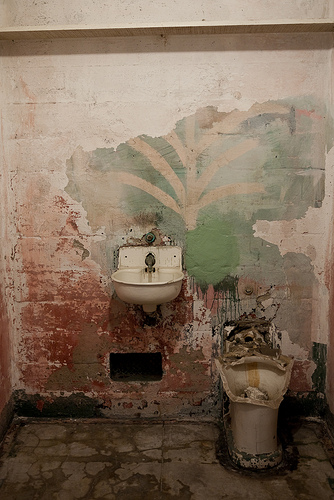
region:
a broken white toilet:
[209, 335, 296, 476]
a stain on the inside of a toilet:
[241, 366, 269, 398]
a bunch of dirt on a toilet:
[221, 436, 267, 476]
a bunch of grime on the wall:
[224, 311, 270, 336]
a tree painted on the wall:
[154, 138, 234, 221]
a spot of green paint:
[185, 221, 246, 290]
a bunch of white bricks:
[58, 87, 106, 131]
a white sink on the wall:
[121, 227, 213, 313]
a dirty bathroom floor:
[69, 434, 152, 486]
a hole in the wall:
[94, 346, 166, 389]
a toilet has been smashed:
[209, 301, 295, 474]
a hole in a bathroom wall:
[101, 341, 170, 389]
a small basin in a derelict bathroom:
[106, 229, 187, 316]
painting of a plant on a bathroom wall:
[108, 98, 294, 233]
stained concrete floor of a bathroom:
[2, 411, 332, 499]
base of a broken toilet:
[211, 351, 300, 473]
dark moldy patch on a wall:
[7, 388, 107, 423]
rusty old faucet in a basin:
[142, 252, 157, 276]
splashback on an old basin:
[116, 244, 184, 270]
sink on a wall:
[100, 233, 202, 305]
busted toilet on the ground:
[211, 347, 308, 480]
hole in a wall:
[105, 348, 169, 381]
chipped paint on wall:
[134, 123, 273, 230]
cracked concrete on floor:
[24, 423, 193, 478]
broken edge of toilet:
[237, 380, 278, 411]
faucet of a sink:
[140, 250, 160, 275]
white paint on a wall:
[82, 68, 176, 113]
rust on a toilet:
[244, 361, 263, 384]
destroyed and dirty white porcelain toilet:
[213, 317, 294, 470]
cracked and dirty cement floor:
[0, 417, 332, 498]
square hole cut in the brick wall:
[107, 349, 164, 383]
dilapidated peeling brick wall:
[3, 32, 333, 416]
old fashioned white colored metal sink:
[109, 244, 184, 315]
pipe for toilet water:
[241, 330, 255, 343]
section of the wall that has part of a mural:
[64, 93, 333, 352]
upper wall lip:
[0, 0, 333, 39]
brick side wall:
[0, 126, 10, 442]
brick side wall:
[317, 128, 330, 441]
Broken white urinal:
[210, 351, 309, 472]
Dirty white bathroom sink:
[110, 243, 184, 314]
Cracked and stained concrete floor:
[3, 415, 333, 496]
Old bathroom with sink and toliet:
[3, 91, 325, 490]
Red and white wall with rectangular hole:
[2, 18, 330, 418]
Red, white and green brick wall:
[2, 6, 333, 418]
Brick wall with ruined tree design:
[3, 2, 333, 416]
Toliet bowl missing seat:
[207, 353, 299, 467]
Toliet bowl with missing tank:
[215, 320, 295, 468]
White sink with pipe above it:
[110, 231, 185, 316]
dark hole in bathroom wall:
[103, 343, 177, 395]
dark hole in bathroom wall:
[103, 344, 177, 391]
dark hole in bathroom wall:
[100, 347, 172, 391]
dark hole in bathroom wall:
[97, 345, 182, 390]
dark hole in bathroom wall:
[96, 345, 171, 387]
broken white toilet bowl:
[217, 318, 293, 468]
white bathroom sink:
[111, 242, 183, 312]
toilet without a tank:
[214, 314, 293, 469]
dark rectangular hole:
[108, 351, 161, 382]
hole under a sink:
[105, 244, 183, 382]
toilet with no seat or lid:
[213, 319, 292, 469]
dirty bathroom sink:
[110, 246, 183, 312]